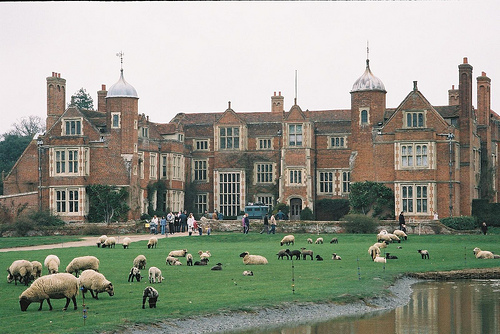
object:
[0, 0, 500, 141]
sky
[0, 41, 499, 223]
building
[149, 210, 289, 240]
people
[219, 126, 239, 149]
window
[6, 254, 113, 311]
sheep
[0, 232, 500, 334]
grass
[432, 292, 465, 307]
water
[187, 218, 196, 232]
shirt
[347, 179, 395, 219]
tree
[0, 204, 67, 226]
pole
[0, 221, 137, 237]
fence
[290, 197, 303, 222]
door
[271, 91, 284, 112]
chimney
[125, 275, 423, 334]
rocks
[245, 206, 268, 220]
car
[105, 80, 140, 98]
dome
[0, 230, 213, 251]
walkway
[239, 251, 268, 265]
lamb